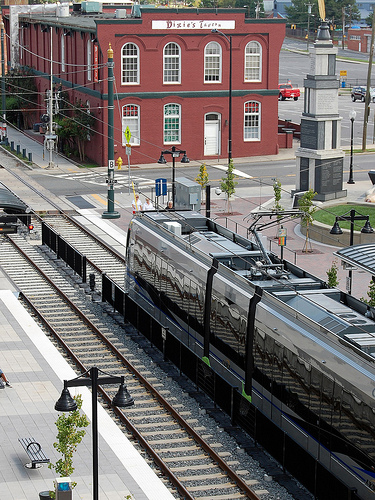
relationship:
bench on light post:
[18, 436, 50, 468] [54, 367, 134, 500]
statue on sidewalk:
[291, 0, 346, 201] [74, 181, 374, 302]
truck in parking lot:
[268, 66, 333, 94] [275, 75, 371, 149]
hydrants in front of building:
[113, 156, 126, 167] [17, 1, 284, 164]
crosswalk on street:
[56, 164, 165, 190] [5, 164, 308, 201]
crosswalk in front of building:
[56, 164, 165, 190] [17, 1, 284, 164]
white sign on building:
[149, 17, 237, 33] [17, 1, 284, 164]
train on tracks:
[122, 205, 371, 496] [2, 213, 279, 495]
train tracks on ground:
[0, 203, 356, 496] [3, 202, 117, 300]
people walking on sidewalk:
[127, 191, 155, 212] [82, 176, 371, 297]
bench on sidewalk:
[19, 434, 50, 470] [4, 384, 147, 497]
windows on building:
[117, 37, 145, 88] [17, 1, 284, 164]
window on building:
[162, 41, 182, 86] [17, 1, 284, 164]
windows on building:
[202, 39, 223, 87] [17, 1, 284, 164]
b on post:
[109, 157, 115, 168] [97, 41, 125, 218]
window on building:
[163, 102, 180, 144] [17, 1, 284, 164]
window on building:
[162, 114, 182, 145] [17, 1, 284, 164]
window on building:
[241, 98, 262, 146] [17, 1, 284, 164]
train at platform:
[124, 208, 375, 500] [0, 280, 219, 498]